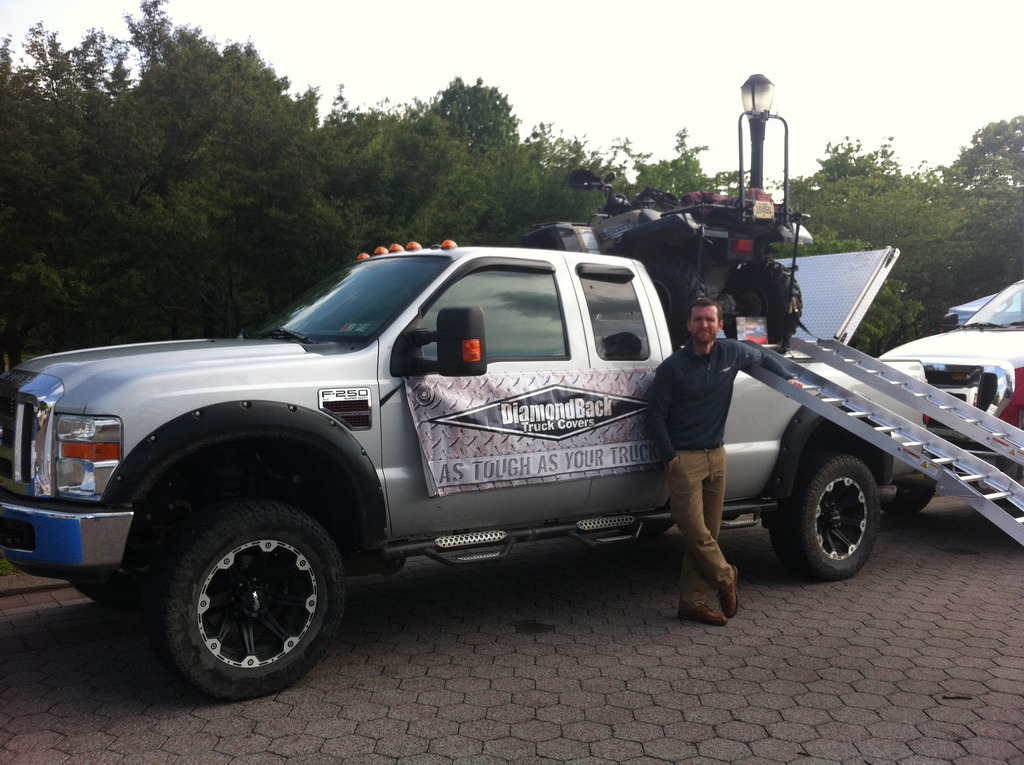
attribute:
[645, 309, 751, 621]
he — brown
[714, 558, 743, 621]
shoe — brown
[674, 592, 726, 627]
shoe — brown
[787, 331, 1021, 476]
ramp — silver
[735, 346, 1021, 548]
ramp — silver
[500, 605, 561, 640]
stain — dark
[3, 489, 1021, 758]
pavement — gray, cobblestone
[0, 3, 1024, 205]
sky — white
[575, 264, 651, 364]
window — tinted, black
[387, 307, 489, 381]
rearview mirror — black, big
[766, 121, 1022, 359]
trees —  big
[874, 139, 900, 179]
leaves —  green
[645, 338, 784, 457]
shirt — black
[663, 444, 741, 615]
pants — brown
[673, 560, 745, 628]
shoes — brown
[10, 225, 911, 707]
truck — silver, large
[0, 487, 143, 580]
bumper — chrome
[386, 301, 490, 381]
mirror — a side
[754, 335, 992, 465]
ramps — silver